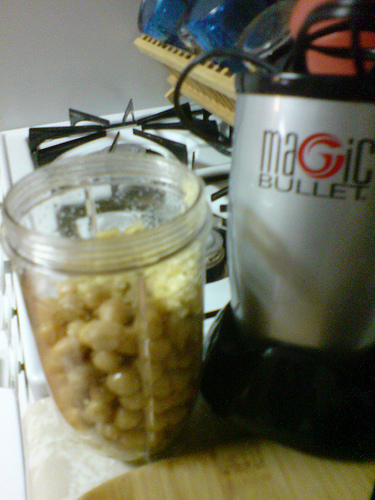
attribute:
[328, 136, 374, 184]
letter — black 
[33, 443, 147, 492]
board — wood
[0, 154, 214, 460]
container — glass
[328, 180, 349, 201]
letter — black 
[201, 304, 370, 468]
base — black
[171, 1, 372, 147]
cord — black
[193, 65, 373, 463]
juicer — black and silver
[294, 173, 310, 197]
letter — black 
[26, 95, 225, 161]
covers — black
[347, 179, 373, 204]
letter — black 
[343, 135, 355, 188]
black letter — black 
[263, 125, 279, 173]
letter — black 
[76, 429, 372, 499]
board — light brown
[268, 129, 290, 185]
letter — black 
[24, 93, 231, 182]
burners — grey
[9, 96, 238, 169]
stove — white and black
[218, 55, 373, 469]
appliance — black 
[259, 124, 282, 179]
letter — black 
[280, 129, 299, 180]
letter — black 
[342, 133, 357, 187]
letter — black 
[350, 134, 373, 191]
letter — black 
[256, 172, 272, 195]
letter — black 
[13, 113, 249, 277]
stove — white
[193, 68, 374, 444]
magic bullet — black and silver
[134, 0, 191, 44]
cup — blue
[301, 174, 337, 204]
letter — black 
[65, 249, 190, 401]
cup — plastic